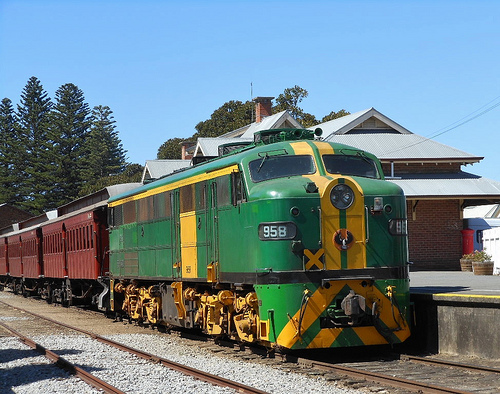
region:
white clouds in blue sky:
[9, 18, 72, 76]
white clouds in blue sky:
[94, 12, 143, 58]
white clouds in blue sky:
[146, 53, 183, 115]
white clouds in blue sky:
[179, 16, 233, 65]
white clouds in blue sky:
[233, 2, 307, 61]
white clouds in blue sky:
[301, 15, 372, 82]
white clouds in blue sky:
[379, 27, 414, 107]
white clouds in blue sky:
[402, 11, 455, 78]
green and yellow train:
[155, 164, 374, 338]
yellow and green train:
[132, 179, 380, 301]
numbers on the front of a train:
[256, 220, 292, 240]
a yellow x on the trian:
[300, 244, 328, 273]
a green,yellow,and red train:
[0, 121, 420, 367]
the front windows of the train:
[243, 147, 384, 184]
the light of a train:
[322, 177, 353, 212]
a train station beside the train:
[135, 92, 497, 278]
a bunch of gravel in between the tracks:
[85, 346, 190, 391]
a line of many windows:
[2, 216, 87, 261]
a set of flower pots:
[455, 250, 495, 277]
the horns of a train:
[254, 120, 326, 144]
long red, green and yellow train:
[2, 123, 430, 369]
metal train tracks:
[1, 295, 276, 391]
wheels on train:
[1, 272, 278, 353]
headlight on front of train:
[322, 178, 369, 217]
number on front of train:
[248, 220, 305, 249]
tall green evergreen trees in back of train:
[0, 73, 131, 225]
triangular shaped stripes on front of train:
[255, 281, 422, 353]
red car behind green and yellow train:
[39, 204, 111, 292]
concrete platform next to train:
[409, 260, 497, 372]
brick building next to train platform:
[343, 103, 495, 270]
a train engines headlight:
[327, 182, 354, 209]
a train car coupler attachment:
[330, 287, 376, 322]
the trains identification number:
[257, 222, 294, 237]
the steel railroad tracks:
[295, 349, 497, 392]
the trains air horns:
[289, 128, 323, 139]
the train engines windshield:
[247, 151, 314, 183]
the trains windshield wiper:
[254, 150, 271, 175]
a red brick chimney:
[250, 95, 275, 120]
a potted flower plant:
[471, 248, 495, 275]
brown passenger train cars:
[0, 208, 105, 303]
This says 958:
[247, 215, 327, 262]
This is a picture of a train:
[105, 185, 345, 305]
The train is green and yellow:
[135, 150, 455, 345]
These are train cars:
[23, 177, 148, 308]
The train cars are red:
[36, 197, 111, 303]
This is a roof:
[360, 89, 482, 191]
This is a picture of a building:
[342, 120, 497, 281]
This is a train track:
[43, 306, 76, 366]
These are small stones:
[94, 358, 116, 383]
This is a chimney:
[242, 96, 279, 129]